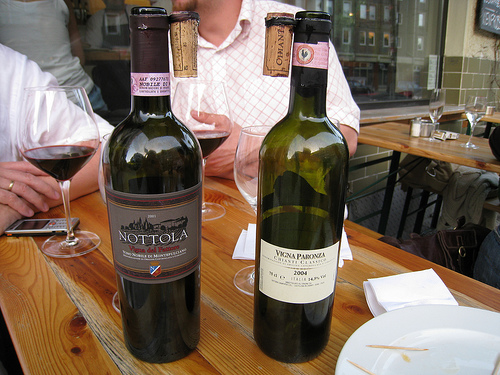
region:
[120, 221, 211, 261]
White writing on wine glass.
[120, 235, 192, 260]
Red writing on wine glass.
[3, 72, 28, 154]
Person wearing white shirt.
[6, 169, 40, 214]
Ring on person's finger.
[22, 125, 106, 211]
Red wine in glass on table.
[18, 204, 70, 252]
Silver phone near glass.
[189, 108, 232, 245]
Wine glass sitting on table.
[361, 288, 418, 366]
White plate sitting on table.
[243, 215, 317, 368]
Bottle of wine on table.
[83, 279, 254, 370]
People sitting at wood table.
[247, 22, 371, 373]
a light green bottle of wine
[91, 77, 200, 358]
a dark green bottle of wine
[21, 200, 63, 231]
a silver cellphone with red button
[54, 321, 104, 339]
light wood colored bar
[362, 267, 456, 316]
a white napkin under plate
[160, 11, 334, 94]
two corks hanging from top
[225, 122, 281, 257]
a empty wine glass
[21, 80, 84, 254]
a semi empty wine glass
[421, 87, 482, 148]
champagne and wine glass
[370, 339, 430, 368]
empty plate with crumbs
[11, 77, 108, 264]
a glass of red wine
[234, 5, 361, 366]
the wine bottle is green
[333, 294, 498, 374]
the plate is white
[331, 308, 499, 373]
toothpicks on the plate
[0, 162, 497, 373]
the table is wooden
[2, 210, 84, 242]
a silver cell phone on the table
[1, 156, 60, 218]
a golden ring on the finger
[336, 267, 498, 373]
a white napkin beside the plate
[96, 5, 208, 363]
the wine bottle says Nottola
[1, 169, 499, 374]
the table is brown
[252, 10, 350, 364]
a dark green wine bottle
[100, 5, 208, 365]
a dark green wine bottle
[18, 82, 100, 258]
a clear glass of red wine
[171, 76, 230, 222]
a clear glass of red wine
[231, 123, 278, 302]
a clear stemmed glass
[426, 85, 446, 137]
a clear stemmed glass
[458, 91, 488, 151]
a clear stemmed glass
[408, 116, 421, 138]
a salt shaker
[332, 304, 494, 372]
a dirty white plate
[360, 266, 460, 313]
a folded napkin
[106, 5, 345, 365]
two bottles of wine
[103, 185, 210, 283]
label on bottle of wine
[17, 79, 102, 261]
glass of red wine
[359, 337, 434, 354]
toothpick on white plate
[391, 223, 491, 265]
brown leather bag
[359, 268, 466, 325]
white napkin under plate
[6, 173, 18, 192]
gold ring on finger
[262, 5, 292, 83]
cork of wine bottle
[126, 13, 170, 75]
foil on wine bottle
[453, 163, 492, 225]
jacket sitting on stool